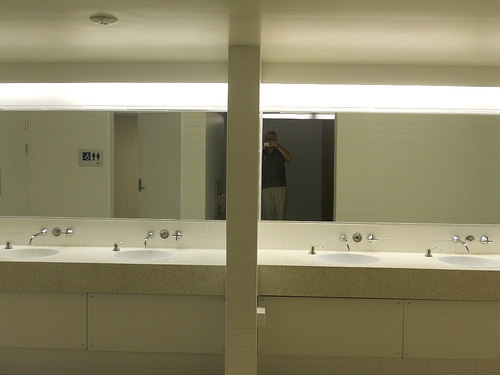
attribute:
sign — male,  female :
[75, 148, 103, 167]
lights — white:
[256, 77, 495, 124]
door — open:
[127, 110, 184, 226]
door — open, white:
[111, 94, 190, 221]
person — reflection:
[262, 130, 292, 221]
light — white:
[262, 83, 497, 114]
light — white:
[0, 82, 226, 112]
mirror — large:
[2, 108, 499, 225]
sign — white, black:
[72, 145, 107, 172]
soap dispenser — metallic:
[3, 234, 19, 254]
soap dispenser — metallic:
[106, 227, 133, 264]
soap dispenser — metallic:
[301, 233, 325, 260]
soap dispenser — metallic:
[423, 238, 448, 278]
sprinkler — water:
[88, 12, 118, 26]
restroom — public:
[0, 1, 497, 365]